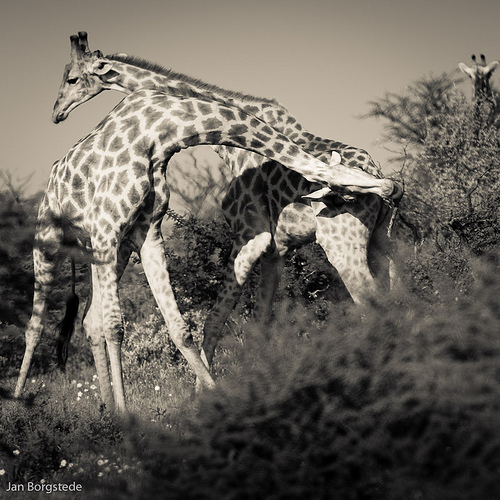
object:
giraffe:
[11, 91, 404, 426]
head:
[49, 33, 105, 125]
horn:
[67, 35, 85, 62]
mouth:
[49, 105, 69, 118]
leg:
[316, 237, 381, 334]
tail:
[54, 244, 82, 375]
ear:
[91, 60, 113, 76]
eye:
[68, 73, 78, 86]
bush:
[273, 350, 464, 480]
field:
[174, 390, 494, 479]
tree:
[427, 145, 490, 243]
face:
[51, 73, 97, 125]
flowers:
[84, 379, 92, 389]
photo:
[8, 6, 464, 498]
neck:
[103, 60, 252, 122]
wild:
[7, 373, 394, 471]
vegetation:
[1, 295, 14, 344]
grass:
[140, 425, 222, 474]